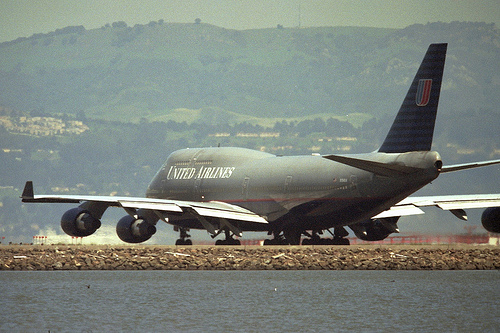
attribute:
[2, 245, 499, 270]
rock — small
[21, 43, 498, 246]
plane — gray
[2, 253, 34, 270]
rock — small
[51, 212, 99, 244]
engine — large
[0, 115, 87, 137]
town — small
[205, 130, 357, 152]
town — small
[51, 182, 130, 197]
town — small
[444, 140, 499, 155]
town — small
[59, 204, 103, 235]
engines — large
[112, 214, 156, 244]
engines — large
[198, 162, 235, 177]
lettering — white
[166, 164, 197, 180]
lettering — white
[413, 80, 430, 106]
sticker — blue, red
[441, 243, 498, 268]
groups — small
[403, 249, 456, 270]
groups — small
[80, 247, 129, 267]
groups — small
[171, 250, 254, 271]
groups — small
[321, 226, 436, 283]
rock — small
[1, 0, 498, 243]
sky — clear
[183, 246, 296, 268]
rocks — small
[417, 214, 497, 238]
engine — large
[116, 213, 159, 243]
engine — large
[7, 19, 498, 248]
mountain — tree covered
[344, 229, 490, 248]
fence — orange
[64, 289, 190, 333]
ripples — small